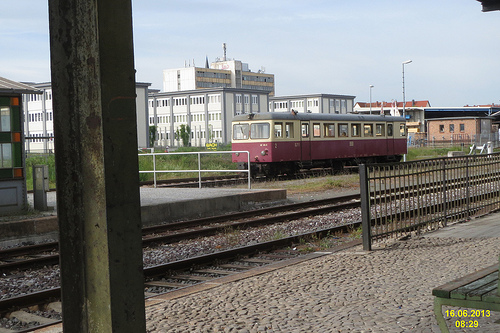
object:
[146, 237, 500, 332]
grey rocks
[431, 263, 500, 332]
bench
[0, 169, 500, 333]
track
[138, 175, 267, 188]
train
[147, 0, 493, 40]
sky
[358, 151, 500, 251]
fence